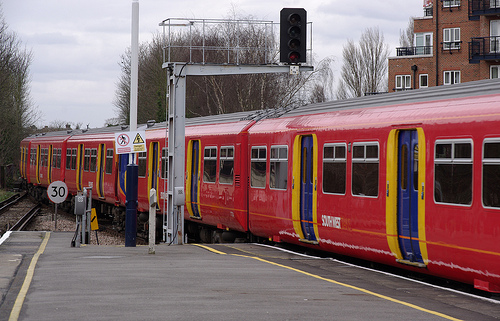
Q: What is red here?
A: The train.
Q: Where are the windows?
A: Side of train.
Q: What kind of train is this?
A: Passenger train.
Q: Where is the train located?
A: In the city.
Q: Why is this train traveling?
A: To bring people places.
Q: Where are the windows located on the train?
A: On the side.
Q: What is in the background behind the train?
A: A brick building.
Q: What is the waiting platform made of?
A: Concrete.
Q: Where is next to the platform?
A: Train.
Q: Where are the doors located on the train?
A: On the side.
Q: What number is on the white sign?
A: 30.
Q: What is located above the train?
A: A light.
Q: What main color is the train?
A: Red.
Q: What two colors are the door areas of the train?
A: Yellow and Blue.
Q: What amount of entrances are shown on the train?
A: Eight.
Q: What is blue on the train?
A: The door.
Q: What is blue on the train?
A: The door.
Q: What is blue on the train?
A: The door.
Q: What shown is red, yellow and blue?
A: A multi car train.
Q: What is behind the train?
A: A brick building.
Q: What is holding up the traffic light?
A: Silver, metal structure.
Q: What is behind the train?
A: A large leafless tree.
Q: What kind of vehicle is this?
A: Train.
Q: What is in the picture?
A: Passenger train.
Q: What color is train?
A: Train is red.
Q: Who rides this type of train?
A: Passengers.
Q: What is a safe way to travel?
A: Commuter train.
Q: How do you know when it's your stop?
A: Conductor calls out stop.